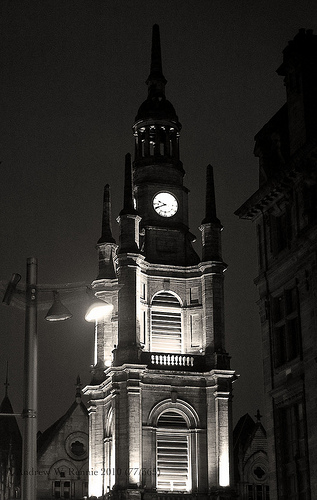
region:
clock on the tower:
[145, 192, 186, 224]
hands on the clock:
[149, 199, 168, 209]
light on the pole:
[79, 301, 117, 326]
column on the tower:
[155, 123, 165, 159]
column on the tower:
[145, 124, 154, 158]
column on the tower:
[137, 123, 146, 152]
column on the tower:
[169, 124, 180, 158]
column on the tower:
[131, 123, 139, 155]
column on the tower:
[200, 271, 235, 355]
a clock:
[144, 188, 185, 224]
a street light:
[81, 305, 117, 324]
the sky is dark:
[9, 65, 87, 135]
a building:
[95, 20, 237, 300]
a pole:
[22, 319, 46, 418]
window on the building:
[264, 305, 300, 366]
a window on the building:
[48, 480, 70, 497]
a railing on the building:
[149, 352, 197, 365]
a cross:
[251, 408, 265, 422]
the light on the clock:
[148, 192, 182, 217]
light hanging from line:
[75, 287, 110, 322]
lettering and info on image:
[4, 459, 170, 489]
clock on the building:
[148, 181, 177, 215]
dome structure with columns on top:
[136, 92, 183, 167]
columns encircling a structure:
[133, 126, 177, 154]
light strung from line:
[44, 291, 70, 323]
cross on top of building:
[2, 353, 11, 399]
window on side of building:
[272, 300, 302, 360]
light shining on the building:
[90, 444, 242, 488]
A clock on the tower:
[160, 196, 172, 214]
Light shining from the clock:
[160, 195, 170, 199]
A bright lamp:
[92, 309, 106, 318]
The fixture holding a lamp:
[50, 309, 66, 313]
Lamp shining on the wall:
[92, 463, 101, 493]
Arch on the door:
[160, 403, 186, 409]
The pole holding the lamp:
[27, 351, 33, 407]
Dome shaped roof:
[145, 103, 165, 116]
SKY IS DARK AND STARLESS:
[5, 1, 315, 177]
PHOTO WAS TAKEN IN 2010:
[94, 460, 123, 477]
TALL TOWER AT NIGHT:
[83, 64, 222, 271]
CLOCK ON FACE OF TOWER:
[148, 188, 183, 224]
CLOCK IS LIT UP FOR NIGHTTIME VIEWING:
[145, 184, 183, 218]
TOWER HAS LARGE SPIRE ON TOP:
[132, 12, 175, 97]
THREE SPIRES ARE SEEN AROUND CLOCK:
[95, 146, 225, 266]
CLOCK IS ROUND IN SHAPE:
[146, 188, 183, 219]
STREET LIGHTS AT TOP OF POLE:
[3, 263, 104, 426]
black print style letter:
[67, 466, 75, 475]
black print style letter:
[84, 468, 88, 476]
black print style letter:
[90, 467, 94, 479]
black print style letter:
[94, 469, 100, 477]